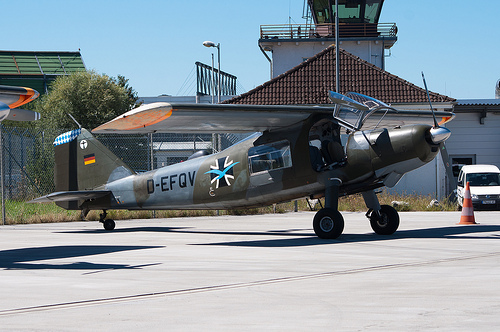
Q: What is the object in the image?
A: An airplane.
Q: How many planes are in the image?
A: One.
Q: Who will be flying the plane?
A: A pilot.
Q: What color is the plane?
A: Green.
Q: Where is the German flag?
A: On the plane.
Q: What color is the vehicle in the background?
A: White.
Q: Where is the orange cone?
A: On the right.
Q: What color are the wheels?
A: Black.